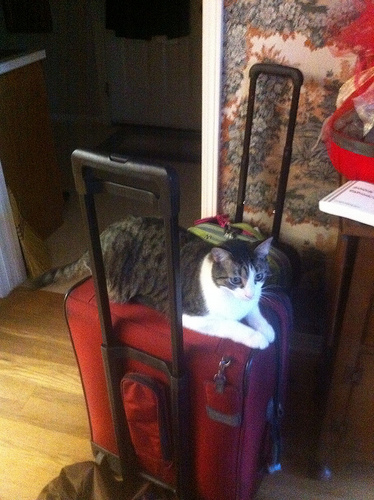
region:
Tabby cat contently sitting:
[86, 215, 282, 354]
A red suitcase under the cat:
[57, 287, 285, 494]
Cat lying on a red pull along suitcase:
[89, 267, 285, 497]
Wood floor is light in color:
[10, 327, 74, 450]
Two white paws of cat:
[229, 315, 275, 352]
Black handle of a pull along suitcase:
[233, 41, 296, 227]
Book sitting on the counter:
[320, 152, 366, 230]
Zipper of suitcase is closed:
[192, 350, 240, 402]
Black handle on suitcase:
[79, 189, 195, 491]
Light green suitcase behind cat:
[192, 220, 255, 246]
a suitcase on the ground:
[56, 142, 294, 497]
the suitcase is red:
[59, 139, 295, 498]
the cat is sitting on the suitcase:
[26, 210, 277, 348]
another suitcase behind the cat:
[193, 54, 303, 295]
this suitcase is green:
[187, 211, 298, 283]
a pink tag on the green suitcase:
[190, 203, 294, 282]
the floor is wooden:
[1, 279, 372, 495]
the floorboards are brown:
[0, 279, 371, 496]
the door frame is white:
[2, 1, 224, 299]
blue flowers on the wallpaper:
[224, 1, 357, 256]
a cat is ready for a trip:
[24, 142, 298, 496]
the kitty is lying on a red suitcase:
[18, 211, 287, 369]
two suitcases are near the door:
[53, 58, 298, 497]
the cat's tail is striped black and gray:
[25, 246, 93, 294]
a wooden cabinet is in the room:
[301, 218, 370, 482]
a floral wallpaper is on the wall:
[224, 3, 341, 333]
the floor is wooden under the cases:
[5, 286, 213, 498]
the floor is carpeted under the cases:
[258, 453, 370, 494]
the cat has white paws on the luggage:
[238, 313, 275, 352]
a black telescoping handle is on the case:
[69, 145, 189, 436]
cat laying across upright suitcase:
[63, 208, 306, 482]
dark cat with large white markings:
[17, 212, 284, 346]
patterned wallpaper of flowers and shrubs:
[228, 1, 312, 213]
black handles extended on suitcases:
[70, 39, 296, 364]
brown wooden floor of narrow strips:
[9, 284, 51, 461]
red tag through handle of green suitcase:
[187, 207, 265, 244]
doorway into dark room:
[4, 2, 200, 292]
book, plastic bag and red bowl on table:
[317, 62, 367, 230]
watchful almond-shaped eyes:
[219, 263, 265, 285]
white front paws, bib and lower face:
[181, 233, 278, 349]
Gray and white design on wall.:
[217, 9, 362, 332]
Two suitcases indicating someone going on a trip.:
[63, 52, 303, 493]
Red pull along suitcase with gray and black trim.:
[57, 149, 287, 495]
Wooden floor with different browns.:
[2, 284, 88, 497]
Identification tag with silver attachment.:
[202, 344, 246, 426]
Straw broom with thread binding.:
[5, 173, 54, 285]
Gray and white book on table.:
[316, 170, 373, 223]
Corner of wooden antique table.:
[306, 217, 372, 487]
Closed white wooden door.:
[94, 3, 197, 136]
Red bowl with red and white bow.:
[322, 7, 372, 180]